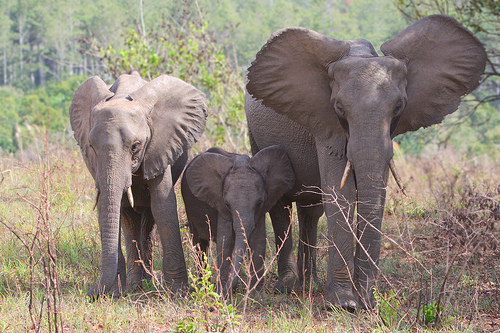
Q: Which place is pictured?
A: It is a field.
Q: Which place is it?
A: It is a field.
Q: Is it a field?
A: Yes, it is a field.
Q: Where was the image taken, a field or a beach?
A: It was taken at a field.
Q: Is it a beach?
A: No, it is a field.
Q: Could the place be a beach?
A: No, it is a field.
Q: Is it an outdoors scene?
A: Yes, it is outdoors.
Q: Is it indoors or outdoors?
A: It is outdoors.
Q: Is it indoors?
A: No, it is outdoors.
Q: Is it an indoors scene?
A: No, it is outdoors.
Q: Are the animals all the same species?
A: Yes, all the animals are elephants.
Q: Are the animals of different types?
A: No, all the animals are elephants.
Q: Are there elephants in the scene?
A: Yes, there is an elephant.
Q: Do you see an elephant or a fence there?
A: Yes, there is an elephant.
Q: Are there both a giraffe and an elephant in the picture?
A: No, there is an elephant but no giraffes.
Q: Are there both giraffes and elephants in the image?
A: No, there is an elephant but no giraffes.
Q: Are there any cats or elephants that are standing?
A: Yes, the elephant is standing.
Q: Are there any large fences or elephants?
A: Yes, there is a large elephant.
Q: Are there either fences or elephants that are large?
A: Yes, the elephant is large.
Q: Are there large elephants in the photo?
A: Yes, there is a large elephant.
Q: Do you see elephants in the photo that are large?
A: Yes, there is an elephant that is large.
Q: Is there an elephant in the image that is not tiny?
A: Yes, there is a large elephant.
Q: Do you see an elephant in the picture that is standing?
A: Yes, there is an elephant that is standing.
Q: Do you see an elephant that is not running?
A: Yes, there is an elephant that is standing .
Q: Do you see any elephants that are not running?
A: Yes, there is an elephant that is standing .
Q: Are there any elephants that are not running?
A: Yes, there is an elephant that is standing.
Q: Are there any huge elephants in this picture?
A: Yes, there is a huge elephant.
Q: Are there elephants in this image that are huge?
A: Yes, there is an elephant that is huge.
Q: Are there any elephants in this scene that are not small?
A: Yes, there is a huge elephant.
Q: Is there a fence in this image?
A: No, there are no fences.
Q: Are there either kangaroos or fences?
A: No, there are no fences or kangaroos.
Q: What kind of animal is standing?
A: The animal is an elephant.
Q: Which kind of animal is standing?
A: The animal is an elephant.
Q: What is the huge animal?
A: The animal is an elephant.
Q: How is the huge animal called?
A: The animal is an elephant.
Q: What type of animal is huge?
A: The animal is an elephant.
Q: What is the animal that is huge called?
A: The animal is an elephant.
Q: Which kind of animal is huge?
A: The animal is an elephant.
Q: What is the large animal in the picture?
A: The animal is an elephant.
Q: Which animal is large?
A: The animal is an elephant.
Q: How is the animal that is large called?
A: The animal is an elephant.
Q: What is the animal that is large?
A: The animal is an elephant.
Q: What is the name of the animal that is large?
A: The animal is an elephant.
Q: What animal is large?
A: The animal is an elephant.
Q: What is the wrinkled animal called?
A: The animal is an elephant.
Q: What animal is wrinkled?
A: The animal is an elephant.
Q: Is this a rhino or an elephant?
A: This is an elephant.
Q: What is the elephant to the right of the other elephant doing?
A: The elephant is standing.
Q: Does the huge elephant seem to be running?
A: No, the elephant is standing.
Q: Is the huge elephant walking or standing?
A: The elephant is standing.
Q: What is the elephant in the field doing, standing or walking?
A: The elephant is standing.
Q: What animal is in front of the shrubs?
A: The animal is an elephant.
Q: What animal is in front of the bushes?
A: The animal is an elephant.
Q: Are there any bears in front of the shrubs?
A: No, there is an elephant in front of the shrubs.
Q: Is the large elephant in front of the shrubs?
A: Yes, the elephant is in front of the shrubs.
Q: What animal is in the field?
A: The animal is an elephant.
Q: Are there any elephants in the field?
A: Yes, there is an elephant in the field.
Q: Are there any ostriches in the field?
A: No, there is an elephant in the field.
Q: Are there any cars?
A: No, there are no cars.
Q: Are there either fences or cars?
A: No, there are no cars or fences.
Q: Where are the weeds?
A: The weeds are on the field.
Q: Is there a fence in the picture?
A: No, there are no fences.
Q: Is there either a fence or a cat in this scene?
A: No, there are no fences or cats.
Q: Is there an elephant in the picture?
A: Yes, there is an elephant.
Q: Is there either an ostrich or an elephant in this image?
A: Yes, there is an elephant.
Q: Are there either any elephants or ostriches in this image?
A: Yes, there is an elephant.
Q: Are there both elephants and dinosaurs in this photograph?
A: No, there is an elephant but no dinosaurs.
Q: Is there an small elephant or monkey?
A: Yes, there is a small elephant.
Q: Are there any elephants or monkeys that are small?
A: Yes, the elephant is small.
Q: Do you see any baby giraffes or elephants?
A: Yes, there is a baby elephant.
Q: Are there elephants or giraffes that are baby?
A: Yes, the elephant is a baby.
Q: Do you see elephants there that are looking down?
A: Yes, there is an elephant that is looking down.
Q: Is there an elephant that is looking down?
A: Yes, there is an elephant that is looking down.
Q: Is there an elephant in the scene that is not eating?
A: Yes, there is an elephant that is looking down.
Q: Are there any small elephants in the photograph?
A: Yes, there is a small elephant.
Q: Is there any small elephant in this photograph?
A: Yes, there is a small elephant.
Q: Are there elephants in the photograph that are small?
A: Yes, there is an elephant that is small.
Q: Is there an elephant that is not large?
A: Yes, there is a small elephant.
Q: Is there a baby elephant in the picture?
A: Yes, there is a baby elephant.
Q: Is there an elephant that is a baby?
A: Yes, there is an elephant that is a baby.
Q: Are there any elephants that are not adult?
A: Yes, there is an baby elephant.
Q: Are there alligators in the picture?
A: No, there are no alligators.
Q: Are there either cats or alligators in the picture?
A: No, there are no alligators or cats.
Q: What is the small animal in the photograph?
A: The animal is an elephant.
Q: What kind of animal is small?
A: The animal is an elephant.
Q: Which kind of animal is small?
A: The animal is an elephant.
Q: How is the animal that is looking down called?
A: The animal is an elephant.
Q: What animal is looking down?
A: The animal is an elephant.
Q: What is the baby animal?
A: The animal is an elephant.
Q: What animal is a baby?
A: The animal is an elephant.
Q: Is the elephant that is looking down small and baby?
A: Yes, the elephant is small and baby.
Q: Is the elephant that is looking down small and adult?
A: No, the elephant is small but baby.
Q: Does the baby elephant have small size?
A: Yes, the elephant is small.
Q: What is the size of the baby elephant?
A: The elephant is small.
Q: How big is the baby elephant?
A: The elephant is small.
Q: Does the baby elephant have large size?
A: No, the elephant is small.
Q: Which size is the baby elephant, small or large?
A: The elephant is small.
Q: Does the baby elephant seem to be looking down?
A: Yes, the elephant is looking down.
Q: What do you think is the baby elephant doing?
A: The elephant is looking down.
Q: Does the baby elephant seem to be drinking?
A: No, the elephant is looking down.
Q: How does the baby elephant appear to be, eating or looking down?
A: The elephant is looking down.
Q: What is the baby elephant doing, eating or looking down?
A: The elephant is looking down.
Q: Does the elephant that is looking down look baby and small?
A: Yes, the elephant is a baby and small.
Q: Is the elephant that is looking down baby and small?
A: Yes, the elephant is a baby and small.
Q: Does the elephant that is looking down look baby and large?
A: No, the elephant is a baby but small.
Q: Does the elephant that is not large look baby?
A: Yes, the elephant is a baby.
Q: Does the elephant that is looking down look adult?
A: No, the elephant is a baby.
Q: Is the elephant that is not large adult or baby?
A: The elephant is a baby.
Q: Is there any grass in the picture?
A: Yes, there is grass.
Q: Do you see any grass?
A: Yes, there is grass.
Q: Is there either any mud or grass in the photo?
A: Yes, there is grass.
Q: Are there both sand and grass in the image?
A: No, there is grass but no sand.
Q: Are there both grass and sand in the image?
A: No, there is grass but no sand.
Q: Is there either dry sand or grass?
A: Yes, there is dry grass.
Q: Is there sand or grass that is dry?
A: Yes, the grass is dry.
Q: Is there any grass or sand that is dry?
A: Yes, the grass is dry.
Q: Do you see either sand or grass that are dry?
A: Yes, the grass is dry.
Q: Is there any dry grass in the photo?
A: Yes, there is dry grass.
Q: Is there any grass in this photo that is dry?
A: Yes, there is grass that is dry.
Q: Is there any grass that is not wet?
A: Yes, there is dry grass.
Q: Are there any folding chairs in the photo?
A: No, there are no folding chairs.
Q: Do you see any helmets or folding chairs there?
A: No, there are no folding chairs or helmets.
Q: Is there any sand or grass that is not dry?
A: No, there is grass but it is dry.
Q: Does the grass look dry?
A: Yes, the grass is dry.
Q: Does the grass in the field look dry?
A: Yes, the grass is dry.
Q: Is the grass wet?
A: No, the grass is dry.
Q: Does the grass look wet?
A: No, the grass is dry.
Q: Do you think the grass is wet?
A: No, the grass is dry.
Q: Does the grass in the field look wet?
A: No, the grass is dry.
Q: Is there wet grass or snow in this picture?
A: No, there is grass but it is dry.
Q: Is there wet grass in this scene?
A: No, there is grass but it is dry.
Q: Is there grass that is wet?
A: No, there is grass but it is dry.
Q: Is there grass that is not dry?
A: No, there is grass but it is dry.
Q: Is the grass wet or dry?
A: The grass is dry.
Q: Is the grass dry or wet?
A: The grass is dry.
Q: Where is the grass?
A: The grass is in the field.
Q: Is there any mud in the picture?
A: Yes, there is mud.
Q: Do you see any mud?
A: Yes, there is mud.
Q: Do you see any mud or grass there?
A: Yes, there is mud.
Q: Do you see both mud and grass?
A: Yes, there are both mud and grass.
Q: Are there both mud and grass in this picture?
A: Yes, there are both mud and grass.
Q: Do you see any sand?
A: No, there is no sand.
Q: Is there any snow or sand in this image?
A: No, there are no sand or snow.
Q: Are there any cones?
A: No, there are no cones.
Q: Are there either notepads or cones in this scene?
A: No, there are no cones or notepads.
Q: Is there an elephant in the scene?
A: Yes, there are elephants.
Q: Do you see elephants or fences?
A: Yes, there are elephants.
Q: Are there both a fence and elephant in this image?
A: No, there are elephants but no fences.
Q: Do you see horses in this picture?
A: No, there are no horses.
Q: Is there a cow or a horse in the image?
A: No, there are no horses or cows.